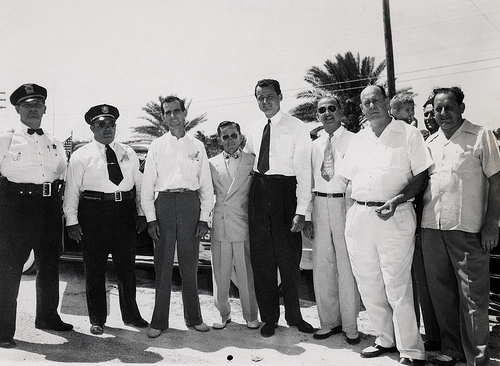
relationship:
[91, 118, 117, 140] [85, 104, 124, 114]
face of man with cap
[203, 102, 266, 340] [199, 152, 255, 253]
short man in suit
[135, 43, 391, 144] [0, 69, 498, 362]
trees are behind group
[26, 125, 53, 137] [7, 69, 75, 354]
bowtie worn by man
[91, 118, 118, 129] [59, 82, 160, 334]
sunglasses are on man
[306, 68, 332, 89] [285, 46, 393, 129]
leaves are from tree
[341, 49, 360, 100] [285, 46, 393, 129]
section of tree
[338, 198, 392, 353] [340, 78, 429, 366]
right leg of man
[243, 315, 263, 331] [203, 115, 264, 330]
left foot of short man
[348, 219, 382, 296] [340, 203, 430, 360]
section of white trouser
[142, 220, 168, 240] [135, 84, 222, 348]
right hand of man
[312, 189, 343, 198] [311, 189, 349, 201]
section of belt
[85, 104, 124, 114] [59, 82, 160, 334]
cap of man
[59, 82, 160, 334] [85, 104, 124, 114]
man wears cap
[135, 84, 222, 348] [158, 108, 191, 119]
man wears sunglasses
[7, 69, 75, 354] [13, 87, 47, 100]
man wearing cap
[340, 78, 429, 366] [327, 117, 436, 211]
man wearing shirt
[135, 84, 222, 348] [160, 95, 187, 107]
man has dark hair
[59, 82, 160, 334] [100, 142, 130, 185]
man wearing tie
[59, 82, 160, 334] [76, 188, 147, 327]
man has on pants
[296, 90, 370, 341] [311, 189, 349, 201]
man wearing belt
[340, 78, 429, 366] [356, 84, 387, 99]
man going bald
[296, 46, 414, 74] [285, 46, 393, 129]
top of tree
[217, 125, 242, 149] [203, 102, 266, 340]
face of short man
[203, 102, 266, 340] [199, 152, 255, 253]
short man in a suit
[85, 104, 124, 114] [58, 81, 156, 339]
cap of police officer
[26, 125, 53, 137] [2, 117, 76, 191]
bowtie on shirt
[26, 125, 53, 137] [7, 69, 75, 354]
bowtie on man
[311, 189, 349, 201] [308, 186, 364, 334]
belt on pants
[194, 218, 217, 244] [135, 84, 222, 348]
left hand of man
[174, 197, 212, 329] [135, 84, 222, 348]
left leg of man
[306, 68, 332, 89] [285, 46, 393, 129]
leaves of tree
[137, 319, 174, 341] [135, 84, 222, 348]
right foot of man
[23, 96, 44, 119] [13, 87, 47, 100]
face of man with cap